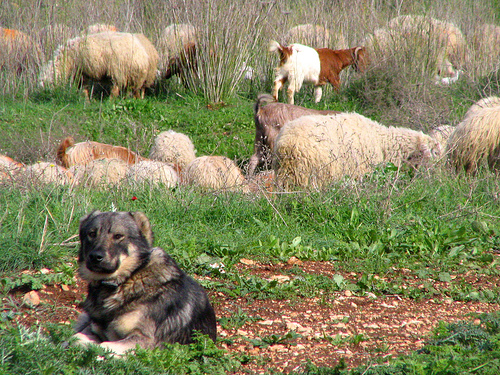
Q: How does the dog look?
A: Sad.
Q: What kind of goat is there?
A: A bi-colored goat.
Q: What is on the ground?
A: Gravel.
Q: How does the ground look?
A: Wet.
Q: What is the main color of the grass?
A: Green.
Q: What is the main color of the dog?
A: Brown.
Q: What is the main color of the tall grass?
A: Brown.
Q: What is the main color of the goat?
A: Brown.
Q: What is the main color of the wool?
A: White.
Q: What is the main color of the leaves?
A: Green.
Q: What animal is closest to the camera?
A: Dog.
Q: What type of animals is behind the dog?
A: Sheep.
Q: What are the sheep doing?
A: Grazing.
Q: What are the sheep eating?
A: Grass.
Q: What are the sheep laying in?
A: Grass.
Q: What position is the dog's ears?
A: Laid back.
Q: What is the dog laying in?
A: Dirt.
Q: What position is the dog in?
A: Laying.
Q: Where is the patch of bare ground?
A: Around the dog.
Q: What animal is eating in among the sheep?
A: Goat.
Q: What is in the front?
A: A dog.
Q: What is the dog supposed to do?
A: Herd sheep.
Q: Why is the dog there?
A: To herd sheep.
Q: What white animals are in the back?
A: Sheep.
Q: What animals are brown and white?
A: Goats.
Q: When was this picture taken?
A: Day time.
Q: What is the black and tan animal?
A: Dog.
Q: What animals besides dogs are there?
A: Sheep.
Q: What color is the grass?
A: Green.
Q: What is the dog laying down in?
A: Dirt.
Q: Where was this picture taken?
A: In a field.